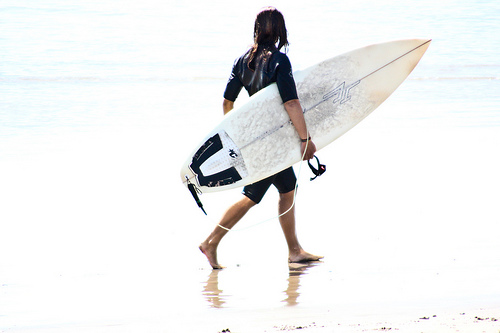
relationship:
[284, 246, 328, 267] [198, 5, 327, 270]
left foot of guy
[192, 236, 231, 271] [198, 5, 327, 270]
right foot of guy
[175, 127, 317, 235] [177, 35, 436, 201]
zline on surfboard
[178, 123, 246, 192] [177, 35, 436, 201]
bottom of surfboard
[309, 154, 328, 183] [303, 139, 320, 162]
sunglasses in hand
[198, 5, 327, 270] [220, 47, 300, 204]
guy in wetsuit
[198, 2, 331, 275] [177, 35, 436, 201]
guy with surfboard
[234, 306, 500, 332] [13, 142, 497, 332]
sand on beach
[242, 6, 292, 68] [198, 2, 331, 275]
hair of guy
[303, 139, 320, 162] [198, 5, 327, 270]
hand of guy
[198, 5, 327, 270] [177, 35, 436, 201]
guy with surfboard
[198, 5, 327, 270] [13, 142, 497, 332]
guy walking on beach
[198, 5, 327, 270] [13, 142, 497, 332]
guy on beach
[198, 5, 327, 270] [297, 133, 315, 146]
guy with wristband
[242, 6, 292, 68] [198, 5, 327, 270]
hair on guy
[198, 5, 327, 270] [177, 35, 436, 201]
guy carrying surfboard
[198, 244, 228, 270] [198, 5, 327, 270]
right foot of guy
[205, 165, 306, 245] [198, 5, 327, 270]
legs of guy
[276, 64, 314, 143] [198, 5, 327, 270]
arm of guy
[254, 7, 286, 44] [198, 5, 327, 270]
head of guy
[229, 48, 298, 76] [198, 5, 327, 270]
shoulders of guy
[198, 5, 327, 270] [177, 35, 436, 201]
guy carrying a surfboard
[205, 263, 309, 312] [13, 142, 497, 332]
shadows on beach